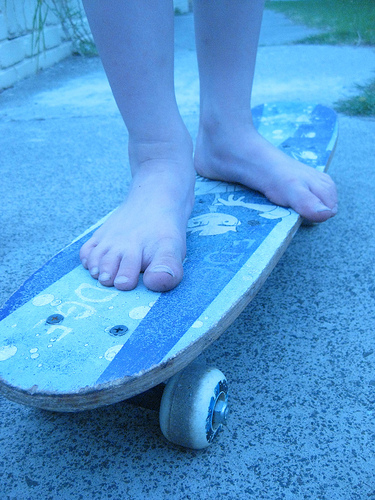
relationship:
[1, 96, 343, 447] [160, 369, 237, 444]
skateboard has wheels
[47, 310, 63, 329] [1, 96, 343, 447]
screw in board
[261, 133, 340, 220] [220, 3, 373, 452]
tose close to ground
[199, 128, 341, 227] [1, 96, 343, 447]
bare feet on board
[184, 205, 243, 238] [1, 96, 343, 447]
logo in skateboard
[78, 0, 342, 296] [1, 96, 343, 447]
man on skateboard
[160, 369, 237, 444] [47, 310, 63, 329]
wheels with bolt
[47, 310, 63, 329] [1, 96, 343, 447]
screw on board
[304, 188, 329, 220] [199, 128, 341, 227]
toe on foot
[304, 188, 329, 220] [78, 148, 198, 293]
toe on foot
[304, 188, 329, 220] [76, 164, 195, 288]
toe on foot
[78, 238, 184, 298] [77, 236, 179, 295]
man has fingure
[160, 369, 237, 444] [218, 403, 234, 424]
wheel has nut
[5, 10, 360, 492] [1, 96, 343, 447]
cement beneath skateboard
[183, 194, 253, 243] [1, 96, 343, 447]
logo on skateboard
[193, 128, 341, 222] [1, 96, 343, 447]
bare feet on skateboard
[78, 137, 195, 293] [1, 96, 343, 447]
foot on skateboard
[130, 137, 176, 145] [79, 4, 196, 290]
line on leg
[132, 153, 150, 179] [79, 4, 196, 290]
line on leg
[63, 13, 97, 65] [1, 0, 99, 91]
weed on wall